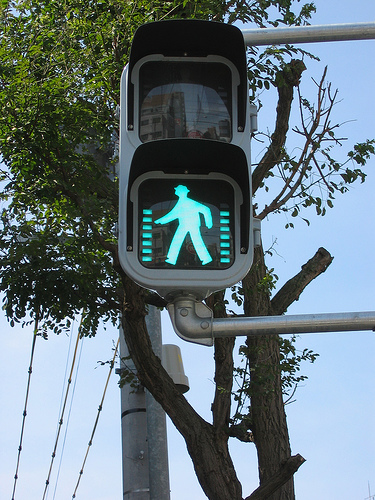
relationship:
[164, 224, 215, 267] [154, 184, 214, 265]
pants on man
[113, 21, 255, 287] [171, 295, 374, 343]
light on pole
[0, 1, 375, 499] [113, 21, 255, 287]
tree behind light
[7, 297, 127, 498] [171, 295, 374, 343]
lines behind pole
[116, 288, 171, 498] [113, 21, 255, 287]
pole behind light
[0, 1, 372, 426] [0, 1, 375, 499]
leaves on tree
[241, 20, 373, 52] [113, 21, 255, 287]
pole holding light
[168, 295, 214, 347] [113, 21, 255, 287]
joint holding top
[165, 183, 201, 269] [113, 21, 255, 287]
man on device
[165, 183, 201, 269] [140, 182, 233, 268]
man on sign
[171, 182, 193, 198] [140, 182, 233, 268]
head on sign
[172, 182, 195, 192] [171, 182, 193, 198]
hat on head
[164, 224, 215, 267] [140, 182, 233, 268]
legs on sign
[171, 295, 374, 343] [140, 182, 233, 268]
pole holding sign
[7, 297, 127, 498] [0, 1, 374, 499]
lines in air